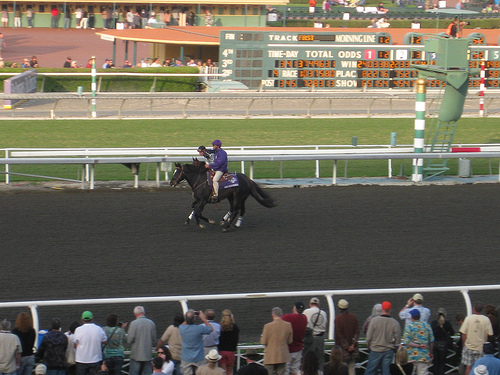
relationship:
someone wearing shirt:
[397, 310, 437, 371] [398, 316, 435, 365]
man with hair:
[125, 302, 162, 374] [132, 301, 147, 318]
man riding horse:
[197, 138, 229, 199] [158, 151, 287, 235]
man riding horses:
[197, 138, 229, 199] [172, 160, 276, 235]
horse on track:
[167, 160, 279, 232] [3, 180, 482, 292]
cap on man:
[76, 308, 93, 321] [78, 308, 94, 323]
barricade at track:
[0, 283, 500, 341] [1, 155, 481, 286]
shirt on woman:
[218, 325, 237, 350] [218, 309, 238, 372]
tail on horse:
[238, 171, 281, 215] [166, 163, 273, 230]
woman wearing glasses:
[155, 346, 172, 373] [156, 349, 168, 355]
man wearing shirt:
[196, 349, 226, 374] [196, 365, 224, 374]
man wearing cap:
[72, 309, 109, 373] [76, 309, 94, 323]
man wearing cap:
[259, 307, 293, 373] [380, 300, 394, 313]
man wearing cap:
[456, 300, 493, 373] [409, 290, 425, 300]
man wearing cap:
[176, 307, 211, 372] [308, 296, 320, 305]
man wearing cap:
[364, 300, 401, 373] [213, 137, 223, 145]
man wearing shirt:
[396, 306, 446, 374] [378, 319, 456, 370]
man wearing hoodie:
[194, 129, 233, 205] [193, 145, 218, 163]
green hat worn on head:
[81, 309, 96, 320] [79, 319, 95, 324]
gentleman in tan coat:
[257, 297, 302, 373] [251, 310, 298, 367]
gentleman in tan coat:
[199, 133, 226, 203] [251, 310, 298, 367]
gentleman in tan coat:
[358, 288, 404, 373] [251, 310, 298, 367]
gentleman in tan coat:
[449, 297, 489, 373] [251, 310, 298, 367]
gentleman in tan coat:
[64, 301, 111, 371] [251, 310, 298, 367]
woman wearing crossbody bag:
[101, 314, 131, 369] [102, 324, 123, 353]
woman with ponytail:
[214, 310, 243, 370] [227, 309, 238, 326]